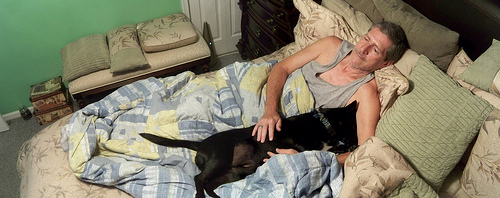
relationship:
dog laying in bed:
[138, 98, 357, 198] [16, 0, 500, 197]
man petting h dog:
[251, 22, 408, 165] [138, 98, 357, 198]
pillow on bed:
[375, 54, 492, 190] [16, 0, 500, 197]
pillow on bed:
[376, 1, 461, 71] [16, 0, 500, 197]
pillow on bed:
[457, 39, 500, 91] [16, 0, 500, 197]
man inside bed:
[251, 22, 408, 165] [16, 0, 500, 197]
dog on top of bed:
[138, 98, 357, 198] [16, 0, 500, 197]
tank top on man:
[301, 40, 353, 111] [251, 22, 408, 165]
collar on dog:
[315, 109, 335, 135] [138, 98, 357, 198]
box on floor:
[30, 75, 66, 110] [0, 112, 38, 198]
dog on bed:
[138, 98, 357, 198] [16, 0, 500, 197]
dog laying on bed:
[138, 98, 357, 198] [16, 0, 500, 197]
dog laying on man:
[138, 98, 357, 198] [251, 22, 408, 165]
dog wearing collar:
[138, 98, 357, 198] [315, 109, 335, 135]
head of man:
[348, 21, 409, 71] [251, 22, 408, 165]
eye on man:
[364, 37, 369, 42] [251, 22, 408, 165]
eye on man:
[373, 48, 378, 53] [251, 22, 408, 165]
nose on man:
[360, 40, 375, 55] [251, 22, 408, 165]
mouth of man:
[355, 51, 362, 60] [251, 22, 408, 165]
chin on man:
[347, 54, 360, 68] [251, 22, 408, 165]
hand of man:
[250, 109, 282, 144] [251, 22, 408, 165]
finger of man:
[267, 122, 276, 142] [251, 22, 408, 165]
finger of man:
[261, 124, 269, 144] [251, 22, 408, 165]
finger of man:
[256, 126, 261, 143] [251, 22, 408, 165]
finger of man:
[251, 122, 259, 138] [251, 22, 408, 165]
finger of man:
[277, 117, 282, 131] [251, 22, 408, 165]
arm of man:
[266, 37, 319, 114] [251, 22, 408, 165]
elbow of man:
[272, 63, 285, 73] [251, 22, 408, 165]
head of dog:
[322, 99, 358, 145] [138, 98, 357, 198]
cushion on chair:
[105, 23, 147, 73] [66, 40, 212, 105]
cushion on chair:
[135, 11, 197, 52] [66, 40, 212, 105]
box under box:
[34, 105, 74, 126] [30, 75, 66, 110]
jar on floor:
[16, 106, 31, 121] [0, 112, 38, 198]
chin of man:
[347, 54, 360, 68] [251, 22, 408, 165]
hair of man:
[368, 21, 409, 64] [251, 22, 408, 165]